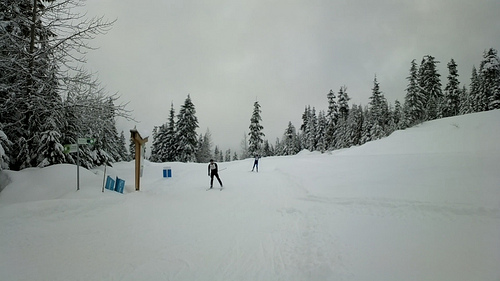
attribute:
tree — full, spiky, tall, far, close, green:
[169, 90, 204, 166]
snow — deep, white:
[270, 153, 400, 225]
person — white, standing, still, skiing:
[196, 153, 233, 195]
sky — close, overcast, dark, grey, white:
[175, 13, 331, 73]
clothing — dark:
[201, 159, 222, 192]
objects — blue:
[103, 173, 124, 193]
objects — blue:
[159, 168, 171, 179]